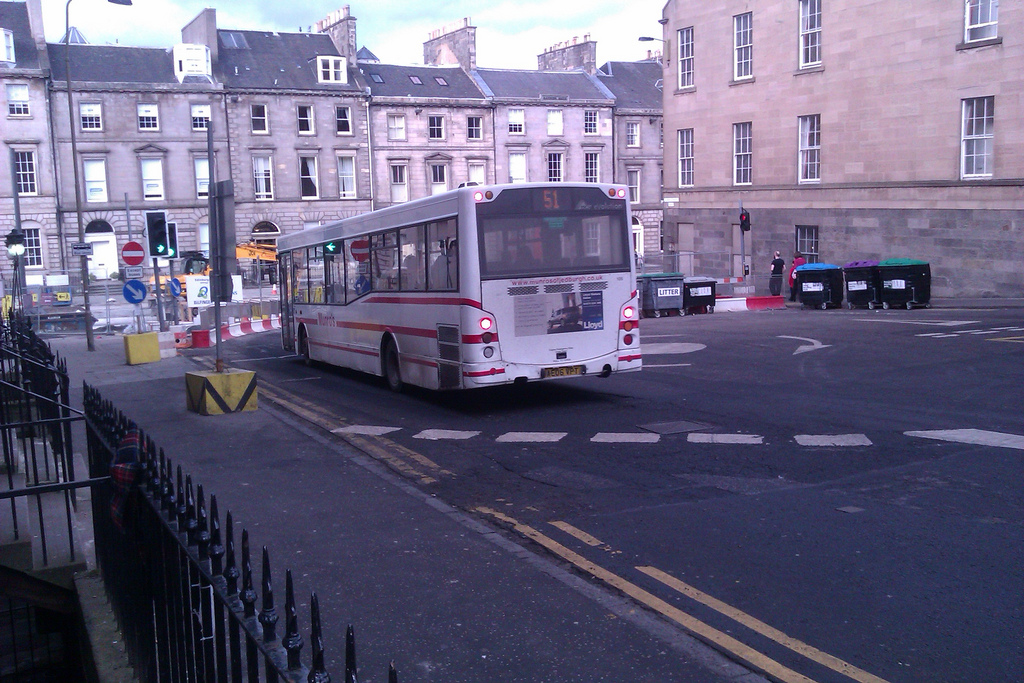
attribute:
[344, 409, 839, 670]
lines — Yellow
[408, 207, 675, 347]
window — Rearview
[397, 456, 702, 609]
lines — yellow 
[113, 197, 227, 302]
light — green 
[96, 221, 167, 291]
sign — red, white 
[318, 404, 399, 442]
square — white 